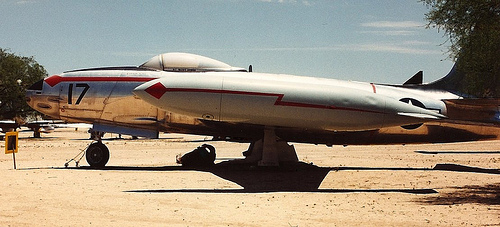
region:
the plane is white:
[27, 46, 469, 188]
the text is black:
[61, 63, 103, 118]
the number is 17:
[60, 73, 88, 107]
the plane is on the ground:
[70, 70, 455, 208]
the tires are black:
[75, 132, 114, 165]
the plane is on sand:
[28, 81, 432, 222]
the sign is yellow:
[2, 122, 25, 164]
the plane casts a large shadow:
[182, 126, 412, 205]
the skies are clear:
[4, 0, 433, 112]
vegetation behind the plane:
[427, 5, 497, 44]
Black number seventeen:
[62, 77, 94, 107]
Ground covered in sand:
[1, 114, 498, 225]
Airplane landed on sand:
[23, 31, 498, 186]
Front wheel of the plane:
[76, 135, 131, 175]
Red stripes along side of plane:
[42, 70, 384, 122]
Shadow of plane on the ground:
[11, 148, 499, 198]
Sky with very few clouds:
[1, 1, 462, 95]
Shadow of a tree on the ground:
[409, 156, 498, 204]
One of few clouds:
[353, 9, 427, 34]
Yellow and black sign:
[6, 126, 21, 171]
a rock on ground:
[166, 202, 195, 224]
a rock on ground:
[230, 199, 256, 219]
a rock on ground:
[289, 198, 313, 213]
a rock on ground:
[313, 194, 330, 224]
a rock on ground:
[329, 189, 345, 201]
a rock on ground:
[351, 175, 374, 200]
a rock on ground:
[391, 194, 403, 215]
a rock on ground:
[421, 170, 444, 200]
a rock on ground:
[456, 199, 471, 219]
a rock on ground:
[460, 169, 476, 204]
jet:
[12, 51, 472, 195]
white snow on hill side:
[342, 16, 379, 43]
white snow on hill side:
[278, 5, 333, 55]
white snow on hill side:
[298, 21, 342, 61]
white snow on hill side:
[251, 2, 292, 39]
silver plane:
[16, 48, 483, 154]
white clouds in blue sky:
[249, 21, 287, 48]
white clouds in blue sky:
[354, 19, 409, 68]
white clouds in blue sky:
[307, 7, 345, 49]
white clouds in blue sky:
[258, 15, 305, 51]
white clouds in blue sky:
[206, 20, 251, 43]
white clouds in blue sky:
[94, 17, 126, 37]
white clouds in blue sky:
[157, 0, 219, 50]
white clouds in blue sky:
[57, 17, 109, 51]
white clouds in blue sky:
[22, 13, 84, 41]